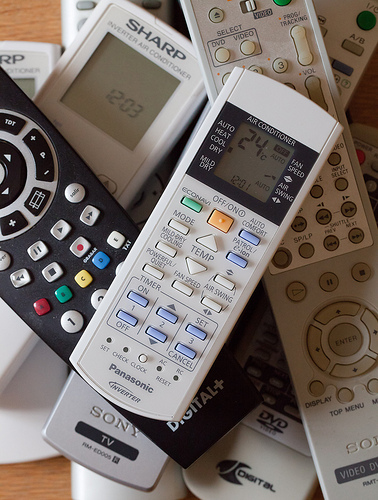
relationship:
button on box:
[173, 342, 197, 362] [66, 64, 344, 422]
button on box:
[183, 320, 210, 339] [66, 64, 344, 422]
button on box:
[154, 303, 179, 322] [66, 64, 344, 422]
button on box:
[115, 309, 134, 326] [66, 64, 344, 422]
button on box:
[142, 324, 170, 341] [66, 64, 344, 422]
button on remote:
[291, 25, 313, 65] [188, 21, 377, 467]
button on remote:
[179, 194, 197, 207] [43, 66, 343, 421]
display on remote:
[186, 100, 319, 225] [43, 66, 343, 421]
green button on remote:
[51, 283, 73, 305] [0, 61, 268, 471]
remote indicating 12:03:
[0, 0, 210, 391] [104, 83, 144, 118]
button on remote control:
[355, 10, 376, 29] [311, 1, 376, 109]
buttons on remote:
[205, 32, 259, 64] [178, 0, 365, 495]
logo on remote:
[98, 360, 157, 409] [224, 78, 285, 203]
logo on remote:
[86, 405, 154, 443] [34, 219, 259, 484]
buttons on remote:
[0, 106, 63, 240] [0, 61, 268, 471]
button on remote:
[239, 228, 260, 244] [43, 66, 343, 421]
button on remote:
[223, 251, 248, 267] [43, 66, 343, 421]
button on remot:
[29, 296, 51, 317] [3, 68, 262, 466]